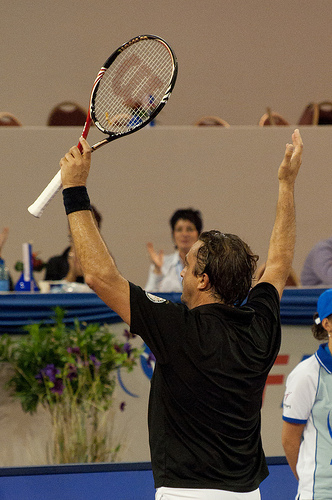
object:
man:
[58, 127, 304, 499]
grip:
[26, 167, 62, 220]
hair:
[191, 230, 259, 305]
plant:
[0, 305, 156, 464]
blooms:
[144, 351, 156, 369]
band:
[61, 184, 93, 216]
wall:
[0, 286, 331, 499]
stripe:
[280, 414, 307, 425]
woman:
[142, 207, 203, 295]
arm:
[246, 180, 297, 315]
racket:
[26, 34, 178, 221]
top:
[179, 227, 259, 305]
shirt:
[279, 343, 331, 499]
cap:
[312, 286, 331, 327]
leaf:
[101, 335, 112, 345]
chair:
[44, 101, 93, 129]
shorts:
[153, 484, 264, 499]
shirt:
[126, 275, 281, 493]